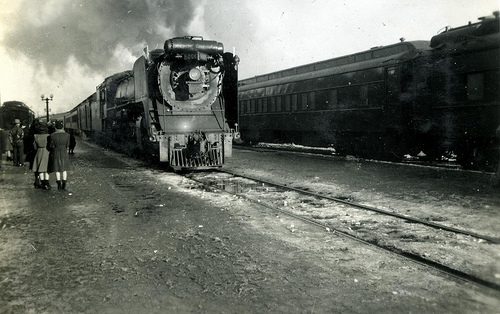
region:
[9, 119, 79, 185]
people going out for the night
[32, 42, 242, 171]
a train sitting on the track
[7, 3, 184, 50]
the smoke in the air above the train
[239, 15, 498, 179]
another train on the track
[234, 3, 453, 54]
the sunny sky above the train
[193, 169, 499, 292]
the track next to the train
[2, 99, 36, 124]
the other train on the other track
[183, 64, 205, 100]
the light on the front of the train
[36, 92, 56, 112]
the light pole next to the train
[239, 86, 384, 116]
the windows on the side of the train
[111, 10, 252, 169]
A steam engine is in black and white.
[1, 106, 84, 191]
A group of people standing next to train.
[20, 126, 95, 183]
Two women are wearing dresses.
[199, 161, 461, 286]
Mud is on top of the train tracks.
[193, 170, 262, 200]
A puddle is on top of the train tracks.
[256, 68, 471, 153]
Another train car is adjacent to another train.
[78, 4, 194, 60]
Steam is coming from a train.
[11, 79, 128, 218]
A train is passing by a group of people.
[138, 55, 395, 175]
A train is passing by train cars.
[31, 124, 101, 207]
Women are standing on muddy ground.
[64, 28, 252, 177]
an old train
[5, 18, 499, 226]
trains in a train yard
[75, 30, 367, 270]
a train on a track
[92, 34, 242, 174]
a smoking locomotive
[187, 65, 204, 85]
headlight on a train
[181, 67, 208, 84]
headlight on a locomotive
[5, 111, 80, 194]
people near a train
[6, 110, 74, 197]
people in a train yard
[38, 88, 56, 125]
lights on a pole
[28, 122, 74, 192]
two women wearing long jackets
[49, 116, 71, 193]
well dressed upper class man walking away from camera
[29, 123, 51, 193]
elegantly and conservatively dressed woman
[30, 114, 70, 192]
wealthy, upper-class couple walking together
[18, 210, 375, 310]
wet and muddy ground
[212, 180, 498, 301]
train tracks in muddy ground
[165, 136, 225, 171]
iron train skirt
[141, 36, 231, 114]
front of heavy train engine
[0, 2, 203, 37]
plume of dark coal smoke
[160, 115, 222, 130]
sun reflected on polished steel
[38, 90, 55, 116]
forlorn telegraph pole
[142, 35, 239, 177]
front of black steam train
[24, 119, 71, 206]
two people standing by train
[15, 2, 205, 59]
smoke coming out from train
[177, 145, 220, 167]
safety ram on front of train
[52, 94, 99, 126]
train cars attached to train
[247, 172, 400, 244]
train tracks on the ground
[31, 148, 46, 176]
skirt on woman standing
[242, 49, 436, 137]
train car on train tracks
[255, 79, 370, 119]
closed windows on side of train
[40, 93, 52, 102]
light post in background